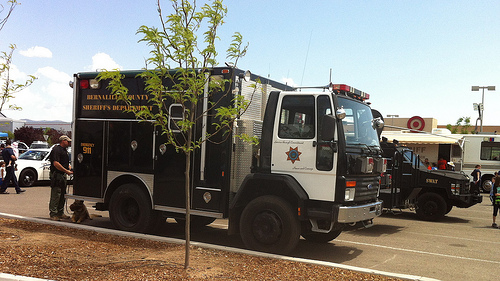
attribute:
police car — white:
[0, 146, 73, 187]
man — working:
[19, 144, 141, 231]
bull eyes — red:
[406, 114, 426, 134]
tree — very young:
[95, 0, 261, 274]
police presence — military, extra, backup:
[376, 134, 498, 227]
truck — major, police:
[69, 68, 382, 256]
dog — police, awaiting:
[43, 190, 114, 240]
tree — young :
[101, 2, 273, 279]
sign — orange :
[406, 113, 425, 132]